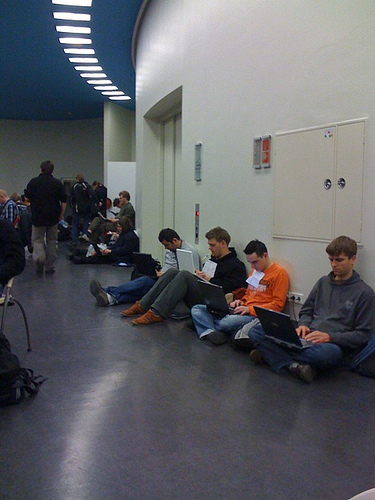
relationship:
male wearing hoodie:
[246, 236, 374, 385] [296, 270, 374, 353]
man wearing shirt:
[191, 237, 290, 351] [229, 266, 290, 319]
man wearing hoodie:
[120, 226, 249, 327] [205, 245, 247, 292]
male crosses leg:
[247, 235, 374, 383] [286, 335, 337, 362]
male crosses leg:
[247, 235, 374, 383] [251, 320, 289, 373]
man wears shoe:
[120, 226, 249, 327] [132, 310, 162, 326]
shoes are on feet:
[122, 305, 158, 325] [115, 301, 160, 330]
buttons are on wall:
[194, 203, 200, 244] [173, 152, 245, 295]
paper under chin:
[238, 270, 268, 290] [253, 264, 262, 268]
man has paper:
[191, 237, 290, 351] [238, 270, 268, 290]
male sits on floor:
[247, 235, 374, 383] [2, 239, 372, 497]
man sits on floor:
[191, 237, 290, 351] [2, 239, 372, 497]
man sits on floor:
[122, 221, 245, 321] [2, 239, 372, 497]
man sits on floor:
[88, 226, 203, 306] [2, 239, 372, 497]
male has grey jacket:
[247, 235, 374, 383] [295, 269, 373, 358]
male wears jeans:
[247, 235, 374, 383] [69, 248, 163, 311]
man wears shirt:
[189, 234, 308, 345] [242, 264, 290, 314]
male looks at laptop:
[247, 235, 374, 383] [251, 302, 315, 350]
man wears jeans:
[89, 228, 200, 307] [179, 297, 259, 347]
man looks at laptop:
[191, 237, 290, 351] [199, 275, 242, 313]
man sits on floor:
[122, 221, 245, 321] [44, 311, 303, 487]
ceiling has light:
[11, 32, 171, 130] [49, 8, 91, 24]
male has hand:
[247, 235, 374, 383] [294, 324, 330, 345]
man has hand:
[191, 237, 290, 351] [228, 293, 251, 319]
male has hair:
[247, 235, 374, 383] [331, 238, 357, 253]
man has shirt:
[191, 237, 290, 351] [230, 265, 296, 318]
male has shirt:
[247, 235, 374, 383] [297, 274, 374, 346]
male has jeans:
[247, 235, 374, 383] [250, 323, 342, 368]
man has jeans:
[191, 237, 290, 351] [193, 301, 241, 339]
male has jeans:
[247, 235, 374, 383] [109, 268, 152, 302]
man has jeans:
[23, 160, 64, 273] [68, 210, 89, 245]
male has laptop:
[247, 235, 374, 383] [249, 308, 324, 348]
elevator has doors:
[137, 100, 188, 284] [159, 114, 183, 271]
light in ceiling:
[68, 50, 97, 71] [35, 20, 133, 100]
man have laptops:
[89, 228, 200, 307] [195, 278, 305, 346]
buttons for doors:
[193, 204, 201, 245] [159, 111, 183, 265]